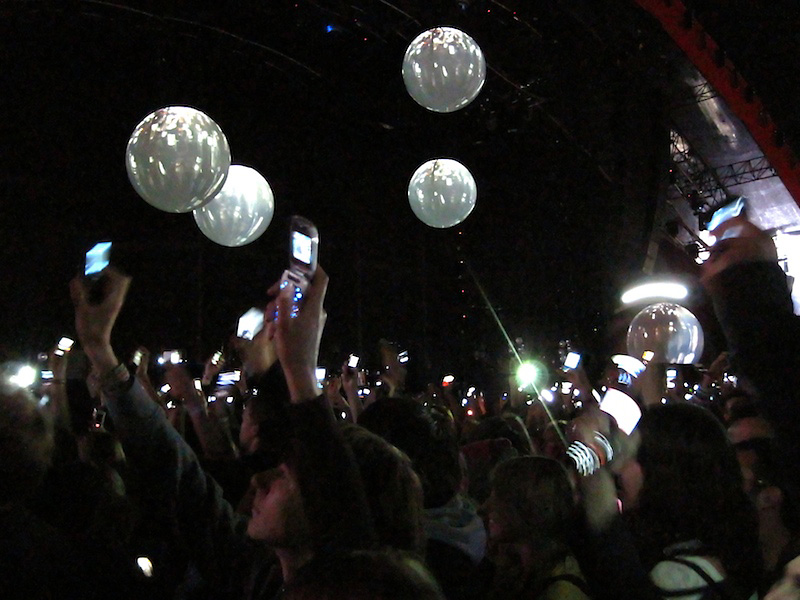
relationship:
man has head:
[245, 265, 422, 598] [241, 423, 427, 555]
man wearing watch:
[81, 262, 422, 599] [73, 343, 148, 398]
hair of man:
[336, 425, 430, 550] [238, 417, 432, 556]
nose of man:
[245, 466, 274, 499] [224, 426, 429, 565]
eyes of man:
[264, 462, 291, 487] [205, 408, 436, 543]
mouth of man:
[246, 497, 267, 525] [228, 414, 430, 565]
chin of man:
[246, 518, 270, 540] [65, 265, 436, 599]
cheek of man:
[266, 484, 288, 525] [65, 265, 436, 599]